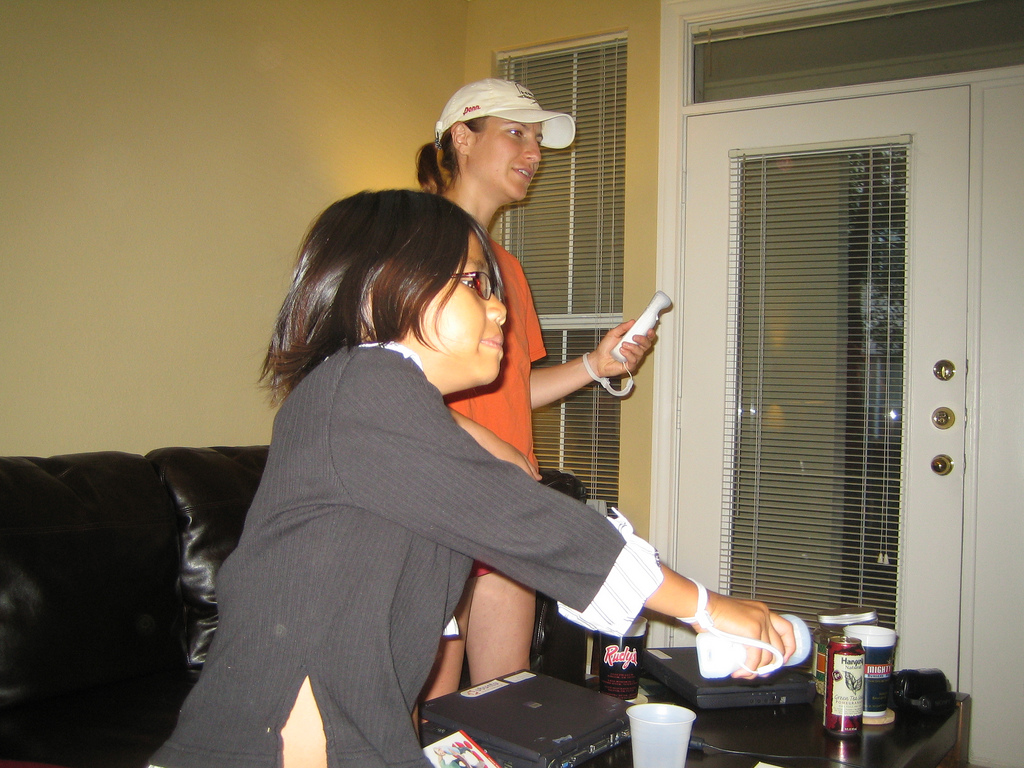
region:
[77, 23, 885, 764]
Two women in a room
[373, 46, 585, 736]
Female wearing shorts and hat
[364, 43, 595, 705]
Woman wearing orange shirt and shorts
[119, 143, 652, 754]
Woman wearing gray shirt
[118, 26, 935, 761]
Women playing with Wii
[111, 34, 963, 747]
Females playing with Wii remotes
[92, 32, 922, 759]
Two women holding Wii remotes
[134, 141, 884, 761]
Woman in grey shirt with Wii remote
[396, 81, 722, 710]
Woman in hat with Wii remote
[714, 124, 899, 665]
mini blinds slanted open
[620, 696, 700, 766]
opaque plastic drinking cup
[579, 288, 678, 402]
hand holding an electronic device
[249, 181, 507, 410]
hair cut at cheek level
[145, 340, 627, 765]
long sleeved gray jacket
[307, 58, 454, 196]
reflective glow of a light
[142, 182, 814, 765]
young girl wearing glasses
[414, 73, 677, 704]
woman wearing a baseball cap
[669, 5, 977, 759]
Entry door with three locks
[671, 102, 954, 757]
Entry door with blinds open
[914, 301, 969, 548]
Set of three locks on front door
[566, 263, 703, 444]
Remote controller for Wii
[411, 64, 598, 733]
Woman dressed in orange shirt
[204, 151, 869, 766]
Lady dressed in gray sweater, white shirt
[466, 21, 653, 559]
Window with blinds in open position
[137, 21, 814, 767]
Two women using Will controller units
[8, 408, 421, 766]
Cushions of black leather couch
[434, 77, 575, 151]
White hat on a woman.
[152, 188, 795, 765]
Brown hair on a girl.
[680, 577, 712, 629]
White strap around a girls right wrist.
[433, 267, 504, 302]
Brown glasses on a girl.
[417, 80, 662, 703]
Woman in a hat and orange shirt.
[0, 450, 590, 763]
A black leather couch.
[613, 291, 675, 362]
White wii remote in a womans left hand.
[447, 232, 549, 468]
An orange t-shirt.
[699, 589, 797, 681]
A girls right hand.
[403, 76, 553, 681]
woman wearing orange shirt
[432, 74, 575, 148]
white hat on woman's head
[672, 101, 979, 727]
white door with gold door knob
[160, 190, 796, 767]
woman with brown hair wearing gray pinstripe shirt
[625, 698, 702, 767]
empty plastic cup on table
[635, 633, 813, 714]
black laptop on table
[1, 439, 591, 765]
black sofa next to wall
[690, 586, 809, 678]
white remote held in woman's hand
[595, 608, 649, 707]
black and white plastic cup